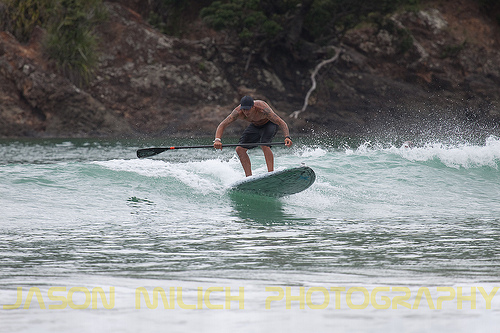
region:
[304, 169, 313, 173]
tip of a board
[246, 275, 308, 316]
part of a graphic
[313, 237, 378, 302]
part of some water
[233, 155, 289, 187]
edge of a board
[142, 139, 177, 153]
part of a padle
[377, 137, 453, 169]
part of a splash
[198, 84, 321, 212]
man standing on surfboard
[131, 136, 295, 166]
two hands on paddle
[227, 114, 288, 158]
shorts on surfing man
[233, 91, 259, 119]
black hat on head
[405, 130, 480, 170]
white top on crashing wave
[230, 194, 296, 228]
reflection of board on water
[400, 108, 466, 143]
water droplets over wave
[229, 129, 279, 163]
bent legs of surfer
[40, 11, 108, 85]
vegetation on rock wall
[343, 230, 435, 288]
light reflection on water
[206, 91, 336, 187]
person in the water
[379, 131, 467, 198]
wave forming in the water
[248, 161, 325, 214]
board below the man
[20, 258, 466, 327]
yellow writing on the photo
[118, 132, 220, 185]
paddle in the man's hand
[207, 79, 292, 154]
man with no shirt on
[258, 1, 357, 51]
tree in the distance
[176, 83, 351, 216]
person surfing in the water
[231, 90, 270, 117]
hat on the man's head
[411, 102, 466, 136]
water in the air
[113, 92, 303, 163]
the man is holding an oar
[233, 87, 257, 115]
the man wears a cap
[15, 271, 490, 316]
the picture is watermarked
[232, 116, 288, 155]
the man wears shorts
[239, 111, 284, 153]
the shorts are black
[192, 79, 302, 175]
the man is leaning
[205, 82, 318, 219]
the man is on a board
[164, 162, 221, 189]
the water is white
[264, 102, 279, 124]
the man has a tattoo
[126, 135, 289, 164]
the oar is black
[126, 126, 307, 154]
Man holding an oar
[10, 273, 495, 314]
Photography company listed at bottom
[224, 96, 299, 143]
Man covered in tattoos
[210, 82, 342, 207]
Man on a wakeboard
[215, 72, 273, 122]
Man wearing a black hat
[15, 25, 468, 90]
Rocky hillside in the background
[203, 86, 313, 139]
Man is not wearing a shirt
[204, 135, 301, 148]
Both of the man's hands are on the oar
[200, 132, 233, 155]
White band on the man's right wrist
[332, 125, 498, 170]
White cap at the top of the wave